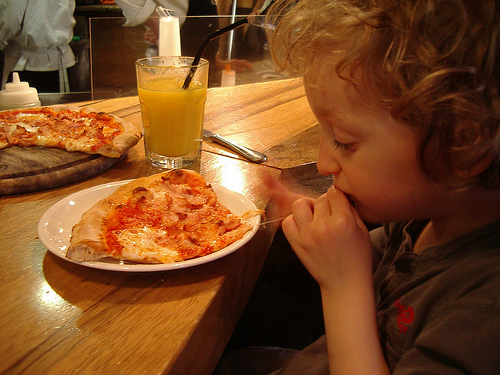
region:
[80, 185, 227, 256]
pizza on a plate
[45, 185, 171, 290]
plate on a table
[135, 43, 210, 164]
glass on a table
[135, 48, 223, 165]
orange juice in a glass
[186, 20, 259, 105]
straw in a glass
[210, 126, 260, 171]
knife on a table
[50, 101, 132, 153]
pizza on a plate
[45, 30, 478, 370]
boy eating piece of pizza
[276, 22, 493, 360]
boy wearing brown shirt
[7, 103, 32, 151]
pizza on a plate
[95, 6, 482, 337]
a child eating a slice of pizza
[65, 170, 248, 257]
a slice of pizza on a plate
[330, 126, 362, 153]
the eye of a child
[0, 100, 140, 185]
a pizza on a wooden serving board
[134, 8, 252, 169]
an orange beverage in a glass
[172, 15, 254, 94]
a black straw in a beverage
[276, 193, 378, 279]
the hand of a child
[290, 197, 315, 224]
the finger of child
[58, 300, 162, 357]
wood grain on a table top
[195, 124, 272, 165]
a metal butter knife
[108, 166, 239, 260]
pizza is in half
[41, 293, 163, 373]
the table is brown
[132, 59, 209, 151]
the juice is orange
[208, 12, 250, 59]
the straw is black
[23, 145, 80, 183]
the board is wooden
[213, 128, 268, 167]
spoon is on the table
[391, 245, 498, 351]
the shirt is brown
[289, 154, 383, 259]
the child is eating pizza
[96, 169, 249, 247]
the pizza looks yummy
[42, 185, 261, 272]
the plate is on the table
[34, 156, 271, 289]
slice of pizza on a plate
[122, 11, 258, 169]
glass filled with juice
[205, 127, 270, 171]
silver metal knife on table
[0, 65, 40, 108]
white lid of a jar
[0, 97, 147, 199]
pizza on a wooden tray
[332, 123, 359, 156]
eye of a person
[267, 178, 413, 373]
arm of a person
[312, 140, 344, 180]
nose of a person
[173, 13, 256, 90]
straw made of black plastic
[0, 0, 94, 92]
person wearing grey shirt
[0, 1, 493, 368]
Photo taken at a restaurant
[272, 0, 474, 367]
Child with curly hair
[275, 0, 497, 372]
Child eating pizza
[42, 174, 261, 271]
Cheese pizza on a plate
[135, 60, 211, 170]
Orange juice in a glass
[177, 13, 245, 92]
Straw in the orange juice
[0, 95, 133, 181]
Pizza on a tray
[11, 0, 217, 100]
Chefs behind the counter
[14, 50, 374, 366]
The counter is wood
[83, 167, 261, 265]
The pizza is cheese